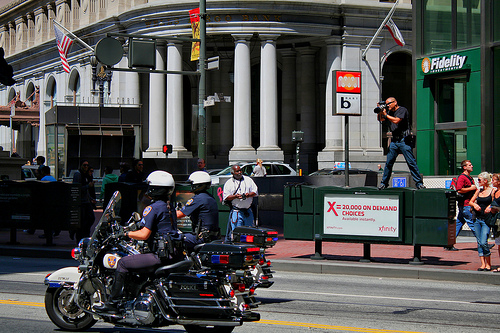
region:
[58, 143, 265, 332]
Two cops riding motorcycles.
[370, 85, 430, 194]
Person taking pictures with a camera.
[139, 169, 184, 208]
Helmet on the head of a cyclist.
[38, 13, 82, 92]
American flag on the side of a building.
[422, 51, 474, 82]
The sign for Fidelity on the building.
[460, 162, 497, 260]
Lady watching the festivities.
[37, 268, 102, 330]
Tire of a motorcycle.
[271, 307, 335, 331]
Yellow lines on the road.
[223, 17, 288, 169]
Columns of a building.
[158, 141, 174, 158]
A walk sign saying stop.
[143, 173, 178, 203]
The helmet is white.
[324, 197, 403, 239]
The sign is red and white.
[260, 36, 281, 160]
The pillar is white.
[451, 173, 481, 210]
The man's shirt is red.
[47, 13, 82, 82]
This is the flag of the USA.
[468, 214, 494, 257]
Her pants are blue.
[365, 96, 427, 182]
The man is holding a camera.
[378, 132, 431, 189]
The man is wearing jeans.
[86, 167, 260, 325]
Two policemen on motorcycles.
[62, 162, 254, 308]
Motorcycles on the street.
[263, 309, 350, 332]
Yellow lines in the road.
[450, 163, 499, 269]
People standing on the sidewalk.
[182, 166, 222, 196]
The officer is wearing a white helmet.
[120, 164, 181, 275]
The cop is riding a motorcycle.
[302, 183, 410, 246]
A sign on the mailboxes.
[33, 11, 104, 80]
An American flag hanging on the building.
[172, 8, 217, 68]
A sign on the pole.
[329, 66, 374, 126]
red and white sign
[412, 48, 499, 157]
green and white building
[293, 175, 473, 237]
green and white sign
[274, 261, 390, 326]
road is light grey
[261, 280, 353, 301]
white line on road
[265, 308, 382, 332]
yellow line on road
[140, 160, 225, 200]
police have white helmets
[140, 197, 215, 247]
police have blue shirts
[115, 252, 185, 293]
police have blue pants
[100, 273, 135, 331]
police have black boots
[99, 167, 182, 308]
officer on a motorcycle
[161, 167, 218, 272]
officer on a motorcycle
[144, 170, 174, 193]
helmet on motorcycle helmet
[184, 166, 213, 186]
motorcycle helmet on officer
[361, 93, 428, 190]
man shooting a video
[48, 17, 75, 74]
USA flag on a pole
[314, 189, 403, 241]
Xfinity poster on side of street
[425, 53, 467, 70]
Name of bank on side of building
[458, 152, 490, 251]
person in red shirt leaning on Xfinity sign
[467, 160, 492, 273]
woman in black tank top ready to cross the road